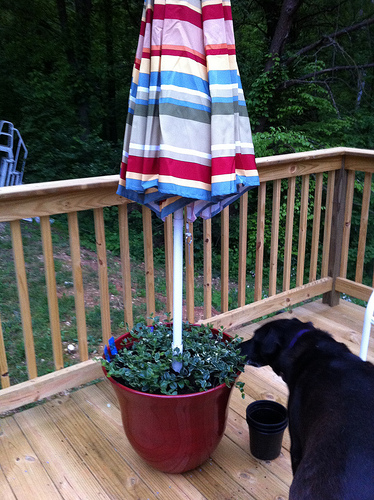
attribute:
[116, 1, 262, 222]
umbrella — colorful, closed, anchored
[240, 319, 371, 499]
dog — black, sniffing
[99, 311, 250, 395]
leaves — green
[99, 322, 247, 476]
flower pot — red, made of ceramic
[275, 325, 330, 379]
dog collar — blue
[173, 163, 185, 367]
pole — white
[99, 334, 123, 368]
flowers — blue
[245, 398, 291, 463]
container — black, empty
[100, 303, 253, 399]
plants — in the pot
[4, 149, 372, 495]
deck — made of wood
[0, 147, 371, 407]
rail — made of wood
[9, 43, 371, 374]
lawn — in bad shape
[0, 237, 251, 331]
dirt — brown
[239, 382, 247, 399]
leaf — green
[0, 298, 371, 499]
floor — made of wood